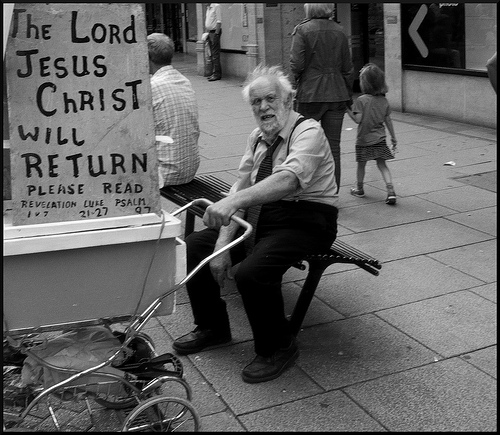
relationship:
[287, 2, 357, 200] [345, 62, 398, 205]
woman holding girl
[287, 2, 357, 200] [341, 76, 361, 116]
woman holding hands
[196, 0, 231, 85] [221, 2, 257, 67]
person standing against wall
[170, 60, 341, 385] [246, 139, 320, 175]
man has shirt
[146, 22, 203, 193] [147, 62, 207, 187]
man wearing checkered shirt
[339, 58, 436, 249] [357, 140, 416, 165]
girl wearing skirt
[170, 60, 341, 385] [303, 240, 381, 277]
man sitting on bench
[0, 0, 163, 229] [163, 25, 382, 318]
cardboard sign next to man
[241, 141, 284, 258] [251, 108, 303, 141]
tie around neck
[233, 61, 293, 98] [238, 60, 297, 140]
hair on head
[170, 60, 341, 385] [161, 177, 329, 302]
man sitting at edge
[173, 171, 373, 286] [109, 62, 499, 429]
bench on sidewalk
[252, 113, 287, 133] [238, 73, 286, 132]
facial hair on face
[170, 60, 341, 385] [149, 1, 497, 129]
man in front of building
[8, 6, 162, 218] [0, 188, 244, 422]
cardboard sign on cart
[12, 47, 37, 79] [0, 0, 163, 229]
letter on cardboard sign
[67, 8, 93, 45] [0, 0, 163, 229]
letter on cardboard sign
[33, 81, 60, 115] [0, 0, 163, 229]
letter on cardboard sign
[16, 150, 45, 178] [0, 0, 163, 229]
letter on cardboard sign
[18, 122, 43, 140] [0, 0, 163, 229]
letter on cardboard sign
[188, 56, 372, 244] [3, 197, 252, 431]
man holding cart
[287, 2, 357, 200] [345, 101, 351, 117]
woman holding girl's hand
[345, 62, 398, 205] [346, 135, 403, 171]
girl wearing skirt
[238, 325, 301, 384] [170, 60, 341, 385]
shoe of man